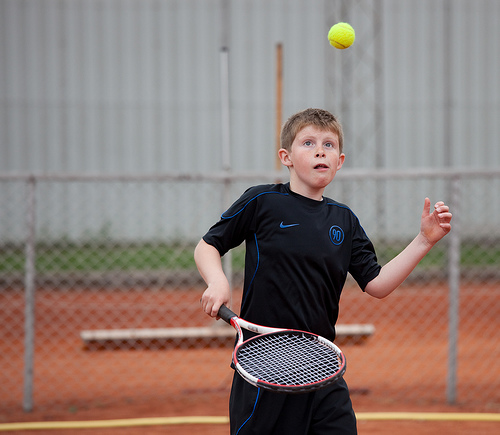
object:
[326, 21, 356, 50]
ball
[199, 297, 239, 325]
tape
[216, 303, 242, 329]
handle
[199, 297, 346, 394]
racket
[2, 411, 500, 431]
line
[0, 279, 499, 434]
ground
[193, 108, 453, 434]
boy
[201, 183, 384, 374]
shirt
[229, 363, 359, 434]
shorts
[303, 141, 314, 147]
eyes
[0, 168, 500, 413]
fence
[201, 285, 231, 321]
hand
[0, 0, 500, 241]
building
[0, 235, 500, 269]
grass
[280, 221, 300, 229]
logo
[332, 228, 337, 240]
number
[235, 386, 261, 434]
stripe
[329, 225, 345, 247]
circle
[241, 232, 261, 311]
stripe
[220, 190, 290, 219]
stripe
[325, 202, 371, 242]
stripe